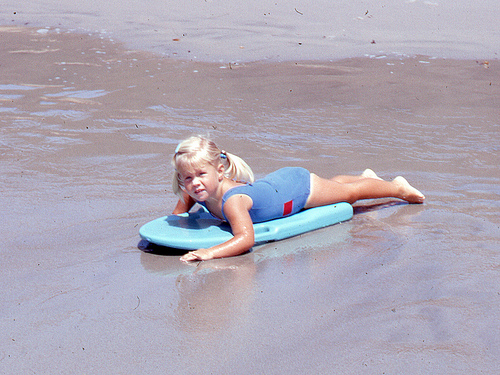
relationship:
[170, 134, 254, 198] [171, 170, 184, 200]
hair styled in pigtails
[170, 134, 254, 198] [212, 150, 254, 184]
hair styled in pigtails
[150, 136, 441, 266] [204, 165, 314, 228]
girl wearing swimsuit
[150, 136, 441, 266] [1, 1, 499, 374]
girl touching water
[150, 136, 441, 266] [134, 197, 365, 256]
girl laying on a boogie board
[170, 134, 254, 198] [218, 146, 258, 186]
girl's hair in pontyails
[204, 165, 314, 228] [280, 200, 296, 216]
bathing suit has a red stripe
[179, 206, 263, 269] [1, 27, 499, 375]
girl's arm on sand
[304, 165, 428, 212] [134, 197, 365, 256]
girl's legs are hanging off board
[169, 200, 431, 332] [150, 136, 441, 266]
reflection of girl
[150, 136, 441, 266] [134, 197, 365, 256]
girl lying on floatie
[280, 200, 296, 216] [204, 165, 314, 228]
red stripe on bathing suit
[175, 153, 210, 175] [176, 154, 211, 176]
bangs are covering forehead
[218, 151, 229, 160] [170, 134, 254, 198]
barrette in girl's hair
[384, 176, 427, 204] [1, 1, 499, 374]
feet resting in water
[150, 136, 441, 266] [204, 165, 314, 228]
girl wearing bathing suit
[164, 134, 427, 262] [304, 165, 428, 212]
baby's skin on leg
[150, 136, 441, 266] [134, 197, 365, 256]
girl on surfboard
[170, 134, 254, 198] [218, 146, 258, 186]
girl's hair in ponytail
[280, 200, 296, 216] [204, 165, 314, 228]
box on bathing suit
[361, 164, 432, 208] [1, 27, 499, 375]
feet are on sand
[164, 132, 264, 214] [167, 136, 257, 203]
girl's face titled up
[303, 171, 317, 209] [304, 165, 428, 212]
line on top of leg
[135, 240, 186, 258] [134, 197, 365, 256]
shadow under board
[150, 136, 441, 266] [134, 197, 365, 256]
girl on a board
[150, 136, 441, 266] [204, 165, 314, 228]
girl wearing a one piece suit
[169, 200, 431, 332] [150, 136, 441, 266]
reflection shows girl